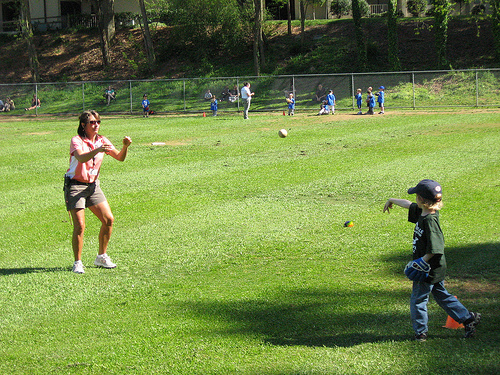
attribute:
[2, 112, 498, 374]
field — green, large, grass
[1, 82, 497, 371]
grass — green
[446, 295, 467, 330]
cone — orange, hidden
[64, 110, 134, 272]
woman — playing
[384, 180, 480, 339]
child — playing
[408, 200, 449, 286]
t-shirt — black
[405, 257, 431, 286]
glove — baseball glove, blue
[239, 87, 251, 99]
top — white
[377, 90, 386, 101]
shirt — blue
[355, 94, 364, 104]
shirt — blue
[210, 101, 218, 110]
shirt — blue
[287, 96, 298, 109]
shirt — blue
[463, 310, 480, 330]
shoe — sport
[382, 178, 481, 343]
boy — small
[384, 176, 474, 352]
child — small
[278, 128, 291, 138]
ball — small, athletic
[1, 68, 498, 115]
fence — chain link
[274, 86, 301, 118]
kid — blue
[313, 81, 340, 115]
kid — blue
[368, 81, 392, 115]
kid — blue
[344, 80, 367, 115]
kid — blue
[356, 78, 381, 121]
kid — blue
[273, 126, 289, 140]
baseball — thrown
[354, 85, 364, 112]
child — small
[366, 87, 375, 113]
child — small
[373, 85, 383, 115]
child — small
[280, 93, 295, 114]
child — small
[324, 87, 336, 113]
child — small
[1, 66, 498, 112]
fence — metal, chain-link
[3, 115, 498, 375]
grass — nicely cut, levelised, green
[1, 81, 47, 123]
people — seated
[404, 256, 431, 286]
mitt — bright, blue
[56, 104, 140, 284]
woman — shoulder length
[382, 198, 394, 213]
hand — left hand , boy's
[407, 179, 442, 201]
cap — child's